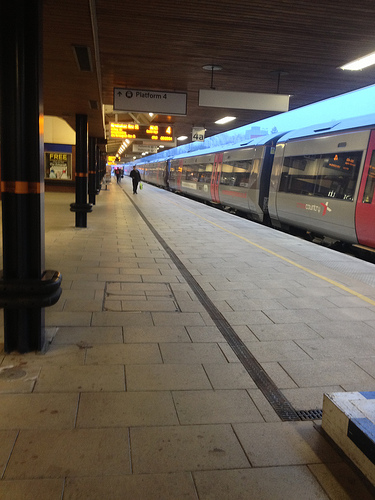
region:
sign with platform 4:
[113, 85, 185, 119]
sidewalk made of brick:
[128, 344, 224, 416]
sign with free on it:
[51, 152, 70, 184]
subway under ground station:
[219, 138, 364, 244]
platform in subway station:
[316, 393, 373, 462]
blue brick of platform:
[340, 426, 372, 455]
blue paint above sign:
[45, 144, 72, 155]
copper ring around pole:
[4, 181, 43, 194]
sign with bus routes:
[107, 120, 174, 144]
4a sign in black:
[192, 124, 210, 143]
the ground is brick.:
[45, 187, 332, 479]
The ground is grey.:
[48, 180, 328, 428]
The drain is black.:
[113, 181, 322, 434]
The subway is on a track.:
[118, 90, 368, 246]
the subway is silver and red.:
[128, 114, 368, 253]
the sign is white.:
[110, 81, 193, 125]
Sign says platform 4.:
[113, 80, 186, 118]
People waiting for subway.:
[113, 160, 143, 199]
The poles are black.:
[64, 91, 94, 232]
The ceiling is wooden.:
[48, 5, 357, 157]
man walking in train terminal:
[126, 156, 150, 195]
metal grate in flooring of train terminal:
[110, 204, 296, 416]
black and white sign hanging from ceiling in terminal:
[108, 76, 190, 124]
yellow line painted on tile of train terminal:
[160, 195, 331, 324]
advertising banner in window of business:
[42, 143, 78, 178]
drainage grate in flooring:
[290, 403, 347, 436]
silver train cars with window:
[159, 131, 365, 245]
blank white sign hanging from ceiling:
[196, 57, 322, 137]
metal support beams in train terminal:
[56, 94, 103, 265]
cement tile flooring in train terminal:
[107, 215, 313, 383]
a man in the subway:
[123, 154, 141, 195]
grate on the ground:
[210, 323, 280, 414]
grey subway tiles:
[45, 390, 236, 477]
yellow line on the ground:
[270, 251, 339, 288]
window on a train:
[280, 140, 348, 200]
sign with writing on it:
[106, 82, 187, 112]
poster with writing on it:
[45, 146, 68, 184]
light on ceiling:
[321, 0, 371, 75]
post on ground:
[65, 108, 95, 228]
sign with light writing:
[104, 122, 189, 145]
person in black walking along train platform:
[127, 162, 147, 195]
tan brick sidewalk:
[97, 231, 217, 481]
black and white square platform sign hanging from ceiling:
[110, 85, 190, 119]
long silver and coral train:
[121, 111, 373, 252]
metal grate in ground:
[287, 405, 326, 422]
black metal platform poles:
[69, 111, 94, 229]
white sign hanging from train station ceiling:
[189, 58, 294, 115]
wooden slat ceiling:
[99, 2, 341, 57]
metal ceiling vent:
[67, 38, 94, 80]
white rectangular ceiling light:
[328, 49, 374, 72]